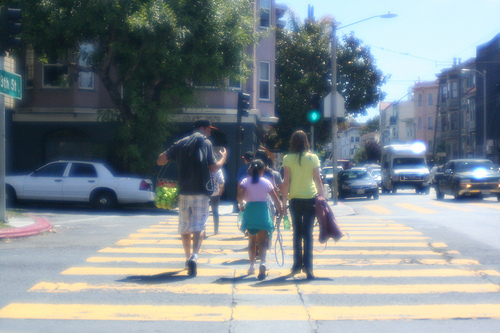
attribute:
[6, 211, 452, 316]
lines — white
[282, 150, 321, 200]
shirt — yellow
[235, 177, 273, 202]
shirt — pink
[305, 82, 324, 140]
light — traffic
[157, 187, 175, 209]
balls — tennis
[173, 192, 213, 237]
shorts — plaid, pair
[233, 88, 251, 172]
traffic light — for the opposite direction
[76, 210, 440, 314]
crossing area — pedestrian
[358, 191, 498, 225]
crosswalk — pedestrian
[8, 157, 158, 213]
car — parked, white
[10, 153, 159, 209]
car — white, parked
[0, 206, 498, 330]
crosswalk — part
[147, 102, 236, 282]
pedestrian — walking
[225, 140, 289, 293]
child — walking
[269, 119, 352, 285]
person — walking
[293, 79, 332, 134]
signal — traffic, green, street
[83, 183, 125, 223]
wheel — rear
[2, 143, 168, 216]
car — parked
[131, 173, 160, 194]
light — rear, brake